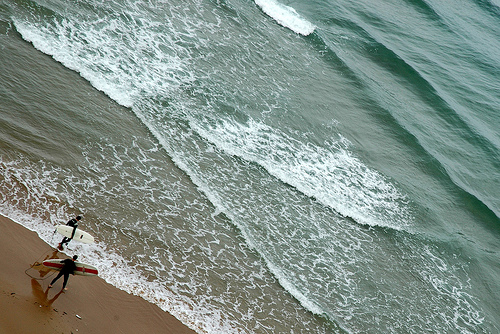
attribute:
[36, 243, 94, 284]
surfboard — red, white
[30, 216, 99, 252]
surfboard — white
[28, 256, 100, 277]
surfboard — white, red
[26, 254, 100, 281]
surfboard — red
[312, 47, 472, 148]
water — green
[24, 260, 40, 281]
board — red, white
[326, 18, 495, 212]
water — green clear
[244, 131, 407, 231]
foam — white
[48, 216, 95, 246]
surfboard — plain, white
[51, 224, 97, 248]
surfboard — white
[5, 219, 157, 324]
area — wet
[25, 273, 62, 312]
reflection — man's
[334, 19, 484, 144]
tides — strong